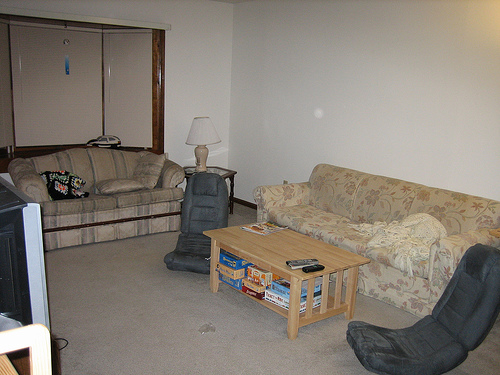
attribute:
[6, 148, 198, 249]
tan sofa — blue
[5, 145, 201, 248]
tan couch — striped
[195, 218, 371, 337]
wood table — blonde, wooden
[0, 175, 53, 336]
flat television — flat-screen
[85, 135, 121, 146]
white car — whtie, toy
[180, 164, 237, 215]
small table — wooden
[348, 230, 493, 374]
black chair — nearest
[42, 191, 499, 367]
carpet — grey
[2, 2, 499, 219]
wall — white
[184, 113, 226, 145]
lamp shade — white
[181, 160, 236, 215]
table — brown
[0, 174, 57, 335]
black tv — silver